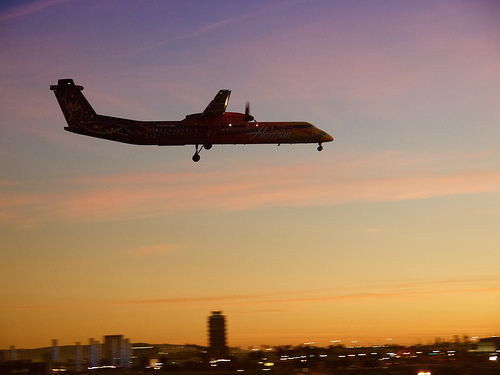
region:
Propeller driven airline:
[26, 53, 405, 203]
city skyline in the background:
[32, 308, 492, 346]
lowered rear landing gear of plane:
[183, 138, 223, 161]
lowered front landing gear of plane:
[305, 138, 340, 164]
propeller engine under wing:
[194, 111, 271, 133]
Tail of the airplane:
[41, 78, 109, 151]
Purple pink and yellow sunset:
[33, 16, 494, 356]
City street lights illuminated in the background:
[206, 329, 498, 373]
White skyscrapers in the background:
[30, 320, 125, 370]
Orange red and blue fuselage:
[107, 103, 296, 145]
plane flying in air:
[45, 67, 335, 174]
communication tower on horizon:
[202, 305, 231, 367]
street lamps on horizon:
[292, 337, 419, 354]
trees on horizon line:
[422, 329, 482, 348]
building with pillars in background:
[7, 331, 137, 366]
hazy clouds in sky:
[13, 147, 498, 220]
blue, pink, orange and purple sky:
[8, 5, 498, 340]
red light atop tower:
[212, 306, 221, 314]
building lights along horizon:
[38, 350, 496, 374]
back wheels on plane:
[186, 139, 216, 164]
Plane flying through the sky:
[29, 65, 374, 165]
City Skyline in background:
[10, 283, 475, 373]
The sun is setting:
[2, 2, 494, 338]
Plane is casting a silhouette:
[41, 50, 360, 172]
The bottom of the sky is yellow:
[27, 252, 498, 348]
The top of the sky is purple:
[7, 3, 497, 133]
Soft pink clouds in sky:
[16, 100, 497, 266]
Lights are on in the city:
[185, 316, 493, 373]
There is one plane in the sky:
[22, 52, 352, 233]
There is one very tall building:
[189, 297, 266, 374]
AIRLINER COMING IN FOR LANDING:
[59, 59, 348, 162]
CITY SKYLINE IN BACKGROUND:
[16, 313, 498, 357]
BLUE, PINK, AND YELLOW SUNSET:
[16, 8, 466, 278]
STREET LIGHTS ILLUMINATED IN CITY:
[274, 336, 497, 356]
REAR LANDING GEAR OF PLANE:
[189, 133, 230, 173]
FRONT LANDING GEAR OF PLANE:
[305, 125, 340, 181]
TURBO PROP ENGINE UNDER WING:
[178, 98, 280, 139]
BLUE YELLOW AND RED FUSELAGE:
[98, 102, 369, 147]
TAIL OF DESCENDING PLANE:
[49, 51, 106, 157]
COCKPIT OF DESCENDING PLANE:
[295, 102, 345, 155]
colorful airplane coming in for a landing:
[49, 69, 338, 159]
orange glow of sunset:
[65, 271, 477, 338]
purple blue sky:
[45, 14, 497, 75]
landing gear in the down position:
[182, 135, 214, 166]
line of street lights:
[270, 347, 445, 358]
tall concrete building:
[202, 301, 234, 356]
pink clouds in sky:
[37, 160, 474, 202]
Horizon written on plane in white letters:
[245, 117, 302, 146]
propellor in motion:
[236, 98, 260, 128]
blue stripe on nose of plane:
[306, 122, 333, 142]